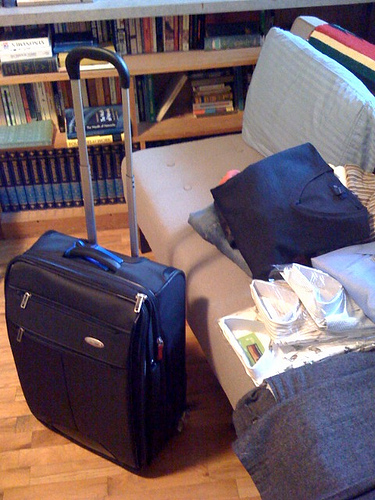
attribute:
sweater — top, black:
[207, 138, 361, 285]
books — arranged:
[57, 94, 144, 152]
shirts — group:
[218, 242, 357, 389]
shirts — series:
[214, 233, 360, 389]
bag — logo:
[81, 330, 113, 353]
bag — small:
[3, 222, 212, 480]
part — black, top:
[58, 38, 138, 89]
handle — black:
[62, 40, 139, 94]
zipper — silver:
[130, 288, 152, 317]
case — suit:
[0, 224, 209, 476]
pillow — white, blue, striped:
[233, 19, 356, 190]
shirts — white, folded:
[213, 230, 345, 393]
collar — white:
[218, 306, 284, 383]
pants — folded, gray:
[223, 344, 354, 498]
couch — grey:
[118, 11, 355, 460]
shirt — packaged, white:
[268, 258, 358, 348]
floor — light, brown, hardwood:
[3, 219, 248, 497]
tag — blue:
[69, 237, 133, 272]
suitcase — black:
[0, 212, 190, 475]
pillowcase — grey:
[183, 184, 265, 281]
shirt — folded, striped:
[240, 270, 338, 349]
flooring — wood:
[4, 434, 83, 498]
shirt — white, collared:
[286, 266, 363, 335]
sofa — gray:
[133, 32, 372, 499]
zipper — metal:
[16, 287, 108, 325]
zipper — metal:
[13, 321, 64, 355]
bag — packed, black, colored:
[4, 231, 186, 466]